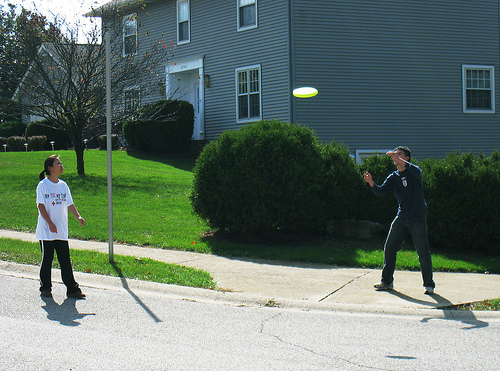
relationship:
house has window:
[81, 2, 500, 162] [118, 11, 141, 60]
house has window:
[81, 2, 500, 162] [173, 1, 194, 52]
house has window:
[81, 2, 500, 162] [230, 2, 263, 35]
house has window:
[81, 2, 500, 162] [118, 85, 142, 127]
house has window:
[81, 2, 500, 162] [230, 63, 266, 124]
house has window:
[81, 2, 500, 162] [459, 61, 499, 119]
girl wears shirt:
[32, 151, 99, 304] [34, 175, 76, 245]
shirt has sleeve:
[34, 175, 76, 245] [65, 184, 77, 211]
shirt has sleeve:
[34, 175, 76, 245] [34, 186, 48, 211]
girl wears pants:
[32, 151, 99, 304] [36, 239, 81, 296]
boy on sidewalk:
[360, 142, 439, 298] [146, 247, 499, 315]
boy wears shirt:
[360, 142, 439, 298] [364, 161, 433, 221]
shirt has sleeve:
[364, 161, 433, 221] [367, 170, 395, 200]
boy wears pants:
[360, 142, 439, 298] [376, 209, 437, 284]